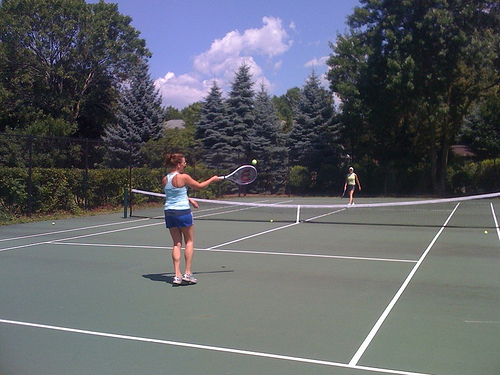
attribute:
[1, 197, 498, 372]
tennis court — green, covered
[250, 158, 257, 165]
ball — tennis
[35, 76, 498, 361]
court — green, tennis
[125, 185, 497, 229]
net — white, black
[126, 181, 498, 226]
fence — black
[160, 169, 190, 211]
top — aqua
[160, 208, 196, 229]
shorts — navy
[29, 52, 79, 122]
trees — green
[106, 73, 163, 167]
trees — green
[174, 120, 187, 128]
roof — shingled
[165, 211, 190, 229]
short — blue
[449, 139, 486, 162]
building — brown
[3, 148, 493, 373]
game — tennis